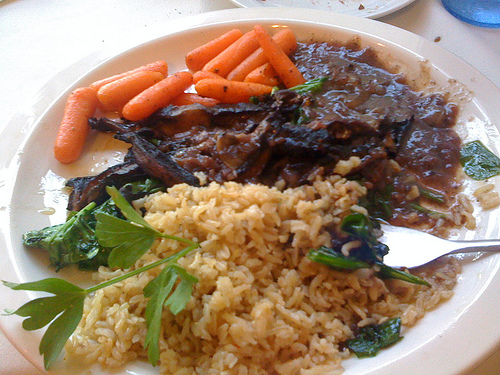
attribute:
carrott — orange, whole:
[66, 93, 83, 150]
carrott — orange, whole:
[92, 77, 122, 82]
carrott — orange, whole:
[109, 78, 149, 87]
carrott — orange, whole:
[134, 88, 166, 101]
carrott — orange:
[195, 41, 227, 51]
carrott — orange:
[227, 46, 244, 58]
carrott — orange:
[249, 55, 257, 65]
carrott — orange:
[256, 71, 271, 79]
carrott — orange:
[264, 36, 274, 53]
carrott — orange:
[211, 83, 237, 94]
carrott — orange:
[197, 72, 211, 78]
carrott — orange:
[181, 95, 200, 105]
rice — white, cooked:
[173, 211, 334, 312]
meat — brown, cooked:
[107, 143, 176, 178]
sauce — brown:
[307, 48, 432, 117]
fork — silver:
[380, 234, 500, 262]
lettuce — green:
[44, 231, 90, 256]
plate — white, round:
[4, 128, 52, 218]